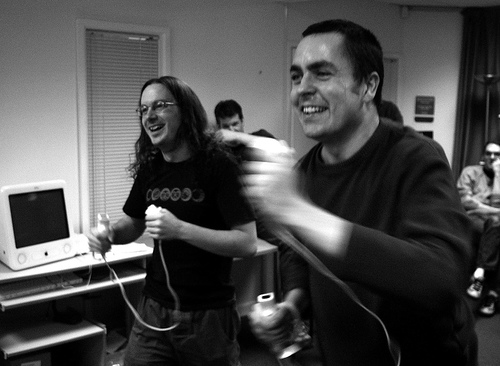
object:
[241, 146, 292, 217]
hand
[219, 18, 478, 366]
man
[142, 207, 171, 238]
fist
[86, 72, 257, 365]
man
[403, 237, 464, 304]
elbow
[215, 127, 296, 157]
wii controllers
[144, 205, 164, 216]
wii controllers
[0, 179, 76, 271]
computer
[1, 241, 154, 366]
desk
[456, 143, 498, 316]
man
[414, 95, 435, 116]
sign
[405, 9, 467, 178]
wall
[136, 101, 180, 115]
glasses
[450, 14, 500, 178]
curtains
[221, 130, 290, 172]
controller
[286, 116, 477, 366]
shirt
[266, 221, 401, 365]
cable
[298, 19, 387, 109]
hair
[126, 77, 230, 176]
hair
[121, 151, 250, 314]
shirt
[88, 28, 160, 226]
blinds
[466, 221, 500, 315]
crossed legged